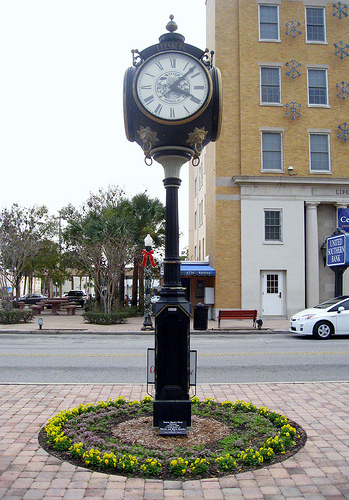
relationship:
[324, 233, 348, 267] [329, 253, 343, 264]
sign for bank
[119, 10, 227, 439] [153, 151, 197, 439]
clock has pole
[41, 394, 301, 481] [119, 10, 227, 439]
flowers surround clock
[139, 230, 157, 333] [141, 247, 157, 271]
lamplight has ribbon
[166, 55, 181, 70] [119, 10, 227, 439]
roman numeral on clock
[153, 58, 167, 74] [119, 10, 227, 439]
roman numeral on clock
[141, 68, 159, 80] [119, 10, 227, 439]
roman numeral on clock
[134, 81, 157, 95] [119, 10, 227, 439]
roman numeral on clock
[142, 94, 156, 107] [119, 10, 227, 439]
roman numeral on clock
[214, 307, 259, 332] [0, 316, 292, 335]
bench on sidewalk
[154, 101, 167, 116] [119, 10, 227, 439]
roman numeral on clock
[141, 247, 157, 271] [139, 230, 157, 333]
bow on lamplight